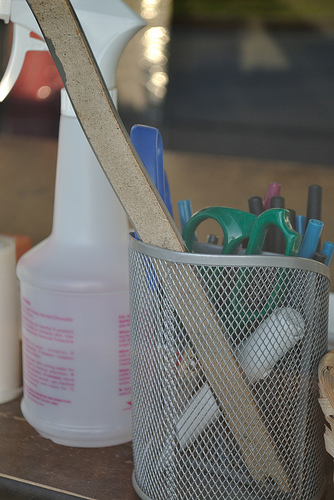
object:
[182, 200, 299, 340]
handle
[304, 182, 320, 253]
caps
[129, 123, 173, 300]
scissors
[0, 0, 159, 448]
bottle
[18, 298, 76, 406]
text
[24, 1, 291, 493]
wood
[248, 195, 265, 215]
cap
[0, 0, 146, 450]
sprayer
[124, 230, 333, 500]
container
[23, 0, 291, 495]
ruler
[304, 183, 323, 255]
pens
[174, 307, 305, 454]
stick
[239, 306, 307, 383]
chalk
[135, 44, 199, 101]
gold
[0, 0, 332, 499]
background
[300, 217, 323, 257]
pen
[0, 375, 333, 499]
desktop